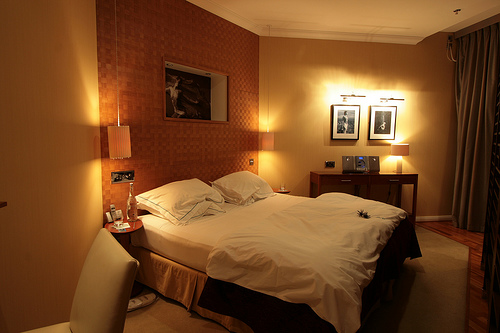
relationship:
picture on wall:
[332, 104, 360, 140] [258, 33, 451, 221]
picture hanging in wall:
[329, 102, 360, 145] [248, 25, 457, 221]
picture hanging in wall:
[365, 100, 397, 145] [248, 25, 457, 221]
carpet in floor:
[382, 273, 459, 332] [465, 260, 485, 326]